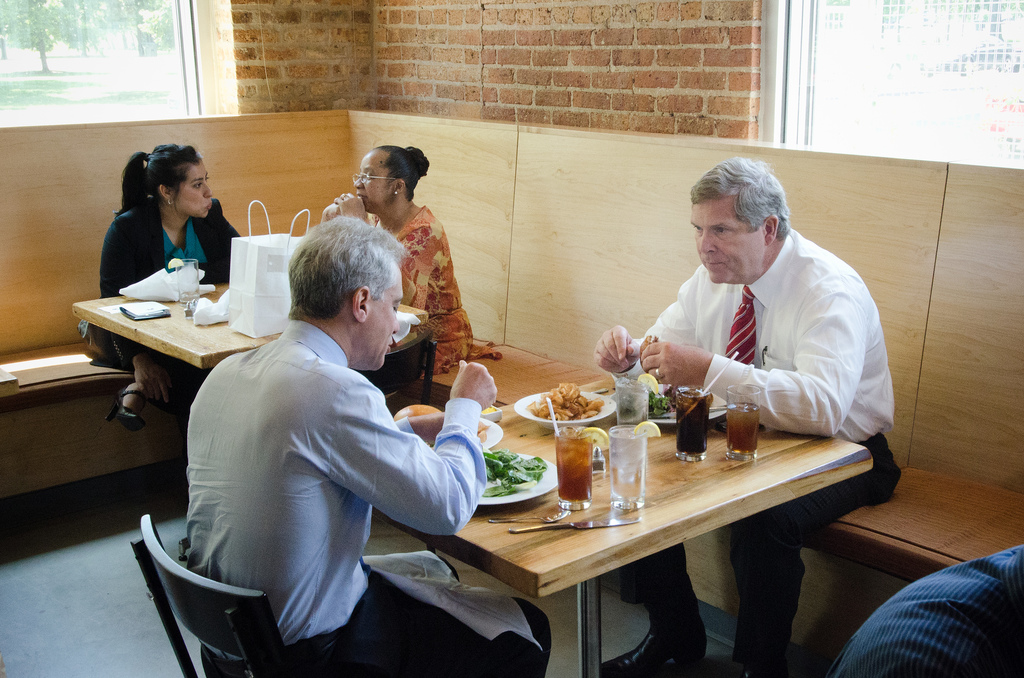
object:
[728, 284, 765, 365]
tie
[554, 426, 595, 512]
straw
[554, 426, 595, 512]
cup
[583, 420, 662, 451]
lemon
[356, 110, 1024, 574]
bench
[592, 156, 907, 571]
businessman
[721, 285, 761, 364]
shirt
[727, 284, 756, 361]
stripes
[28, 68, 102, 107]
lawn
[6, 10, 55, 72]
tree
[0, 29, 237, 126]
window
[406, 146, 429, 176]
bun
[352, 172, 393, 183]
glasses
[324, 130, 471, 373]
person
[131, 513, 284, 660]
chair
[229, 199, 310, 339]
bag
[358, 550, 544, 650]
napkin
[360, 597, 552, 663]
lap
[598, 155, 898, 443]
man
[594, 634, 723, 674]
shoes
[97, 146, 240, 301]
woman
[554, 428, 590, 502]
tea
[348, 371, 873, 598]
table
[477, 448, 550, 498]
plate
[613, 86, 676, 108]
red brick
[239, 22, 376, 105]
brick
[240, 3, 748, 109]
wall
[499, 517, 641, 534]
knife